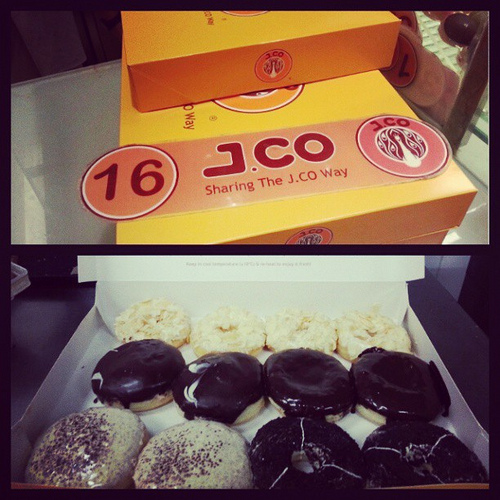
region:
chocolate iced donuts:
[87, 331, 454, 431]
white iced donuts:
[110, 290, 404, 347]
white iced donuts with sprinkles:
[24, 407, 252, 498]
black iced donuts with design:
[244, 410, 479, 497]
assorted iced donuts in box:
[21, 294, 483, 491]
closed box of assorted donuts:
[104, 13, 474, 240]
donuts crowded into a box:
[20, 284, 492, 496]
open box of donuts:
[15, 261, 477, 491]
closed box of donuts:
[82, 21, 482, 239]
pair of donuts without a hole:
[27, 394, 252, 498]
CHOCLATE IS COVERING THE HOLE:
[300, 362, 315, 379]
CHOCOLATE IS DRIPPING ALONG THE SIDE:
[230, 405, 245, 415]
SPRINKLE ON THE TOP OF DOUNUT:
[165, 450, 190, 465]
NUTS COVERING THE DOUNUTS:
[205, 310, 210, 340]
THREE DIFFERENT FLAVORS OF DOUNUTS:
[186, 302, 256, 489]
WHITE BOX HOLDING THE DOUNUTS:
[305, 286, 346, 296]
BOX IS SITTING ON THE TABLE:
[52, 325, 67, 365]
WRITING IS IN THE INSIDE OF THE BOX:
[165, 256, 315, 266]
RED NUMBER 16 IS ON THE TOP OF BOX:
[91, 131, 171, 226]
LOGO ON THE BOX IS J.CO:
[206, 125, 333, 170]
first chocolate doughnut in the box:
[93, 339, 184, 409]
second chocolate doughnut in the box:
[176, 348, 268, 425]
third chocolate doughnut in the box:
[261, 346, 353, 422]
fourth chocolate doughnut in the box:
[349, 350, 451, 422]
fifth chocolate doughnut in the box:
[251, 411, 370, 498]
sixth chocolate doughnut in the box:
[361, 415, 491, 496]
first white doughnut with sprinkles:
[32, 404, 143, 492]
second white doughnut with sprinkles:
[129, 422, 254, 498]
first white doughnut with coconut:
[114, 299, 194, 347]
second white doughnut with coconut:
[184, 303, 266, 353]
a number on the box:
[83, 150, 172, 214]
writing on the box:
[200, 133, 356, 191]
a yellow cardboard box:
[126, 74, 466, 238]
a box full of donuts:
[37, 305, 494, 497]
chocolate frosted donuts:
[101, 347, 450, 407]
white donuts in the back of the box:
[113, 300, 420, 350]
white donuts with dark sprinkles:
[46, 415, 237, 494]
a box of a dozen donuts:
[43, 301, 475, 494]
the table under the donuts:
[25, 283, 86, 345]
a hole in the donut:
[290, 452, 322, 469]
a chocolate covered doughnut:
[83, 340, 176, 405]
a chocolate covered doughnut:
[182, 350, 266, 422]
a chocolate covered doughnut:
[269, 350, 348, 414]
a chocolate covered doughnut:
[347, 349, 440, 418]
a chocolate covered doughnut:
[359, 418, 473, 488]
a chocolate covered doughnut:
[257, 422, 363, 489]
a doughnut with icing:
[143, 415, 253, 488]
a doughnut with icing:
[21, 410, 141, 481]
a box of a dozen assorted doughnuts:
[41, 284, 480, 498]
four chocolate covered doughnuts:
[83, 339, 445, 414]